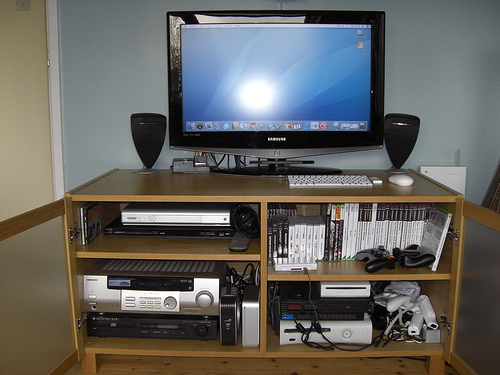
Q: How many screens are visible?
A: One.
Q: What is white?
A: The wall.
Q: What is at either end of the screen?
A: A pair of vases.